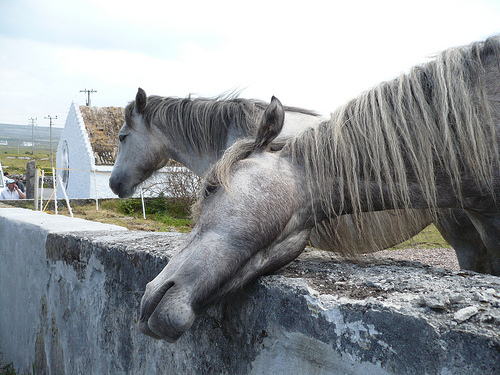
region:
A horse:
[65, 94, 193, 200]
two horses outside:
[90, 80, 328, 366]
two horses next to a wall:
[37, 81, 433, 363]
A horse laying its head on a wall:
[82, 115, 365, 353]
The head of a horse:
[91, 78, 166, 218]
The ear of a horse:
[236, 84, 331, 178]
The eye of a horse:
[176, 149, 244, 216]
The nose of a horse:
[101, 159, 141, 204]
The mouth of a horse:
[131, 264, 238, 357]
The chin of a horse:
[161, 305, 209, 350]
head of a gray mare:
[98, 85, 195, 199]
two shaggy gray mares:
[100, 35, 487, 352]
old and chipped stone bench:
[8, 201, 136, 351]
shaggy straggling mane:
[285, 41, 482, 268]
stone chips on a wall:
[380, 264, 497, 339]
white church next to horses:
[32, 81, 112, 205]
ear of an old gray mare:
[245, 88, 290, 160]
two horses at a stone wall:
[77, 72, 438, 349]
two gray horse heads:
[85, 62, 355, 344]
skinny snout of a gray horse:
[125, 262, 203, 340]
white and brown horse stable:
[55, 100, 202, 198]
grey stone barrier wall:
[1, 211, 498, 374]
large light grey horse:
[108, 88, 455, 268]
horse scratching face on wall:
[135, 33, 497, 340]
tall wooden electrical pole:
[27, 114, 38, 157]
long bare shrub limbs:
[126, 163, 201, 218]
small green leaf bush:
[113, 193, 174, 215]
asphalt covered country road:
[1, 154, 55, 164]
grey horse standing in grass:
[109, 83, 439, 254]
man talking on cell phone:
[2, 176, 29, 205]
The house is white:
[76, 144, 78, 153]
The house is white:
[86, 166, 96, 182]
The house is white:
[83, 131, 88, 150]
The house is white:
[72, 180, 84, 192]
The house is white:
[83, 167, 93, 180]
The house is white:
[68, 163, 93, 175]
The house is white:
[83, 170, 97, 175]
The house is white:
[77, 177, 92, 190]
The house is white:
[82, 158, 92, 170]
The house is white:
[79, 169, 85, 181]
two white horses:
[80, 33, 483, 340]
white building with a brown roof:
[58, 77, 236, 194]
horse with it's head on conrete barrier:
[125, 123, 312, 347]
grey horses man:
[344, 56, 477, 233]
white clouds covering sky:
[71, 24, 284, 84]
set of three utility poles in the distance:
[13, 76, 107, 148]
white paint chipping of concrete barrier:
[36, 205, 108, 312]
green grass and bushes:
[124, 197, 197, 227]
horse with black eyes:
[200, 172, 223, 208]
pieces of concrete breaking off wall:
[410, 278, 484, 331]